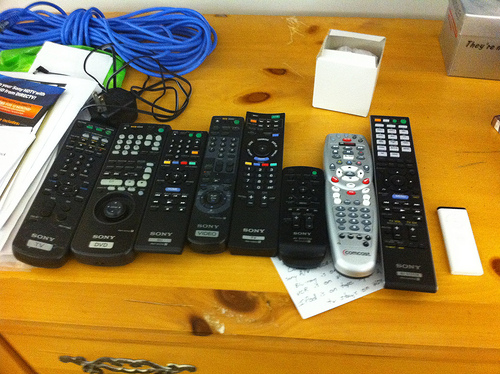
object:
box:
[312, 29, 386, 117]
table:
[0, 12, 500, 373]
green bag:
[1, 45, 127, 89]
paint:
[204, 307, 228, 334]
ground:
[445, 154, 475, 172]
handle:
[59, 355, 194, 374]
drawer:
[0, 319, 499, 374]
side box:
[439, 0, 500, 81]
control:
[12, 111, 437, 293]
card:
[270, 245, 383, 319]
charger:
[81, 41, 193, 128]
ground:
[185, 61, 227, 93]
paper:
[270, 245, 383, 320]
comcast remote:
[323, 133, 378, 279]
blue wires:
[0, 1, 217, 78]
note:
[285, 260, 382, 308]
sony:
[93, 235, 116, 239]